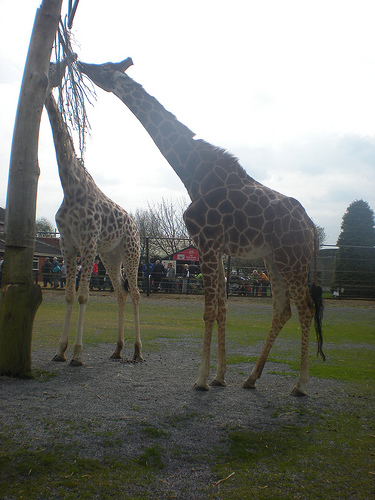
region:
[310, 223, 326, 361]
long tail on giraffe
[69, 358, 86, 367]
hoof on giraffe's body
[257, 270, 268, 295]
person in orange shirt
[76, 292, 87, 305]
knee on giraffe's body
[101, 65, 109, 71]
eye on giraffe's face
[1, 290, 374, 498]
grassy pen with giraffes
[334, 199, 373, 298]
evergreen tree growing from ground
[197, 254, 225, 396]
the giraffes legs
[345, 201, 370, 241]
the bush is tall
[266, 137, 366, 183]
clouds in the sky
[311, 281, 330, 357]
the giraffes tail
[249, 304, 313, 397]
back legs of the giraffe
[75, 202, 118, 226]
brown pattern on the giraffe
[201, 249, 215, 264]
brown spot on giraffe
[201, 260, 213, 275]
brown spot on giraffe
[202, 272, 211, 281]
brown spot on giraffe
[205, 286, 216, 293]
brown spot on giraffe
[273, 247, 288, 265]
brown spot on giraffe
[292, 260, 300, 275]
brown spot on giraffe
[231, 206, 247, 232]
brown spot on giraffe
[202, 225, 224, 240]
brown spot on giraffe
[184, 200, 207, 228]
brown spot on giraffe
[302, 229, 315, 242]
brown spot on giraffe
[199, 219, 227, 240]
Small brown spot on a giraffe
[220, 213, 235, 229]
Small brown spot on a giraffe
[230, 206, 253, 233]
Small brown spot on a giraffe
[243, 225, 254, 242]
Small brown spot on a giraffe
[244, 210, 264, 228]
Small brown spot on a giraffe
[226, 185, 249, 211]
Small brown spot on a giraffe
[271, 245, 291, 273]
Small brown spot on a giraffe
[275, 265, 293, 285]
Small brown spot on a giraffe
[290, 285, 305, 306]
Small brown spot on a giraffe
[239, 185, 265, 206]
Small brown spot on a giraffe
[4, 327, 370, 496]
grey stone gravel in the grass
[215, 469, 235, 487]
a bare twig on the ground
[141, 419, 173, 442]
a patch of green grass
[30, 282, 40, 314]
a knothole outgrowth on a tree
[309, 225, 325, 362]
the long tail of a giraffe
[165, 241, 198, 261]
the triangle facade of a building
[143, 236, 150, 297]
a brown wooden pole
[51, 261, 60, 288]
a woman wearing a blue shirt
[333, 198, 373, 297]
a tall bushy tree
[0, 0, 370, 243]
light of daytime sky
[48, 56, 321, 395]
two giraffes eating from tree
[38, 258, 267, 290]
people behind enclosure fence